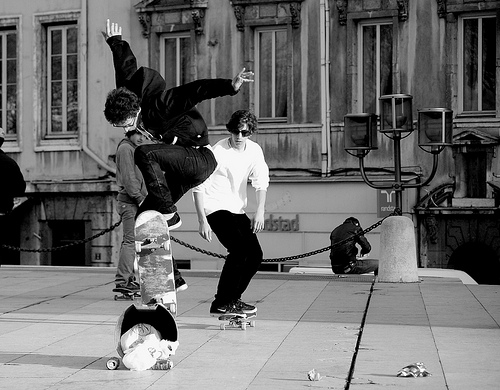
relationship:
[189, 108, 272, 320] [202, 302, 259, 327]
boy riding skateboard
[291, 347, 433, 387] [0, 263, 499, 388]
garbage laying ground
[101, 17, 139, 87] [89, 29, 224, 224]
arm part of man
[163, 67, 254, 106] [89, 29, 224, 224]
arm part of man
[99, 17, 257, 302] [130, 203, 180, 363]
boy on skateboard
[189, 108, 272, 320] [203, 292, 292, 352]
boy on skateboard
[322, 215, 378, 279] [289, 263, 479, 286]
man sitting on ledge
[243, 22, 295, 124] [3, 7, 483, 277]
window on building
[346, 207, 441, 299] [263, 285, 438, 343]
concrete structure on ground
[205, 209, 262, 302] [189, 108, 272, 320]
pants on boy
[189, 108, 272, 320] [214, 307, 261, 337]
boy riding a skateboard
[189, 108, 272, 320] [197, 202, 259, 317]
boy wearing pants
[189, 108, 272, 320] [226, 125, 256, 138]
boy wearing sunglasses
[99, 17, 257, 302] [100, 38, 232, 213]
boy wearing hoodie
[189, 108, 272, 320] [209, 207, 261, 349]
boy wearing pants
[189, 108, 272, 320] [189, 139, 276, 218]
boy wearing shirt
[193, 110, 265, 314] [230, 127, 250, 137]
boy wearing glasses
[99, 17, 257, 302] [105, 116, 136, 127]
boy wearing glasses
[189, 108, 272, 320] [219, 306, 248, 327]
boy riding skateboard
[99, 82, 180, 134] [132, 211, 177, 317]
boy riding skateboard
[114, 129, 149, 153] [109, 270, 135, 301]
boy riding skateboard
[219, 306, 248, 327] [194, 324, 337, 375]
skateboard on sidewalk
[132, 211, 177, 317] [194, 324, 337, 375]
skateboard on sidewalk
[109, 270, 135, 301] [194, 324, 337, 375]
skateboard on sidewalk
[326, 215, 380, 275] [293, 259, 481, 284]
man sitting on wall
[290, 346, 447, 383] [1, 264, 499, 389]
trash on sidewalk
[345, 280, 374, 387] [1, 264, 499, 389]
crack on sidewalk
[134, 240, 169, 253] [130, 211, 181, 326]
wheels on skateboard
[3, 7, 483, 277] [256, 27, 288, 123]
building has window